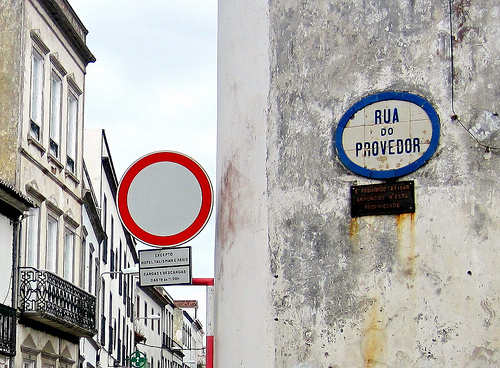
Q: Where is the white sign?
A: Left side of building.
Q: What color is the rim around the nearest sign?
A: Blue.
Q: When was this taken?
A: During the day.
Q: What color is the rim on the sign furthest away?
A: Red.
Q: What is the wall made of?
A: Stone.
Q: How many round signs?
A: Two.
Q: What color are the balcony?
A: Black.